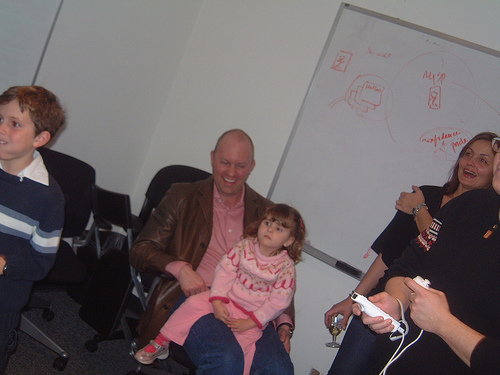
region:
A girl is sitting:
[135, 204, 305, 372]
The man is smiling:
[210, 129, 255, 196]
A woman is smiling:
[455, 133, 491, 186]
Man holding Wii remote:
[350, 275, 448, 335]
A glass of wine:
[326, 317, 343, 347]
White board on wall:
[260, 3, 498, 281]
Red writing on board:
[331, 46, 498, 168]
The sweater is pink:
[210, 236, 295, 328]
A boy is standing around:
[0, 84, 66, 369]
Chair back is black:
[32, 146, 94, 237]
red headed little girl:
[176, 199, 333, 374]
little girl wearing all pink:
[140, 190, 333, 366]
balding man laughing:
[202, 113, 262, 213]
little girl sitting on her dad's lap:
[131, 123, 331, 368]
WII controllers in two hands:
[341, 250, 469, 365]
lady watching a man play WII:
[326, 118, 497, 371]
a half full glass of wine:
[317, 277, 359, 362]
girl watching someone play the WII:
[163, 186, 325, 343]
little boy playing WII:
[1, 55, 90, 322]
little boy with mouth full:
[0, 71, 86, 303]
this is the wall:
[120, 18, 202, 58]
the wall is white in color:
[114, 30, 185, 74]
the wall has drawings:
[343, 42, 440, 124]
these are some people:
[4, 85, 494, 367]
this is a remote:
[343, 291, 409, 325]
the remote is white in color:
[351, 295, 368, 307]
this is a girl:
[231, 196, 311, 338]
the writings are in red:
[321, 38, 451, 144]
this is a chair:
[162, 168, 184, 175]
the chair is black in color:
[163, 163, 189, 178]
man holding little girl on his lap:
[131, 128, 304, 373]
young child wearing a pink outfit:
[133, 205, 301, 373]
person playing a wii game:
[351, 131, 498, 373]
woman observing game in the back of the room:
[324, 132, 493, 373]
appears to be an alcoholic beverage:
[321, 314, 351, 350]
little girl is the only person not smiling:
[254, 206, 308, 257]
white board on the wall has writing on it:
[267, 5, 498, 280]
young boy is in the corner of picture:
[0, 85, 66, 374]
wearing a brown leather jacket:
[130, 176, 297, 323]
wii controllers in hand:
[350, 274, 433, 374]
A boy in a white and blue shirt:
[0, 85, 66, 288]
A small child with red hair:
[136, 202, 304, 369]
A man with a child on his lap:
[132, 122, 302, 372]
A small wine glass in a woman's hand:
[323, 311, 345, 349]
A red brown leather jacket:
[134, 184, 276, 336]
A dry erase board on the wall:
[255, 3, 492, 280]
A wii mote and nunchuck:
[348, 274, 432, 371]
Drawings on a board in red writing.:
[325, 65, 397, 127]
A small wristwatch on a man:
[271, 317, 296, 334]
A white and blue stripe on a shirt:
[0, 204, 65, 258]